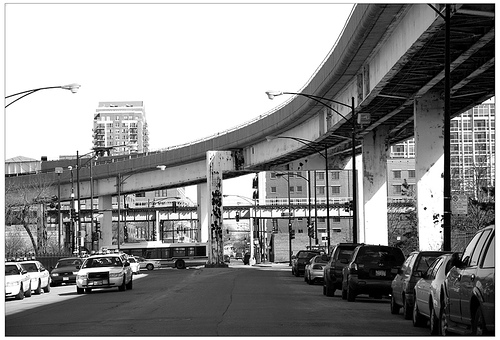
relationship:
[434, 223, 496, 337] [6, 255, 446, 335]
car parked on road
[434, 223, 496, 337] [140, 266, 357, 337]
car on street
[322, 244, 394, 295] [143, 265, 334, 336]
car parked on street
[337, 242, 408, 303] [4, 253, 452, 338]
car parked in street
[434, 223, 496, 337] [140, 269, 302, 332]
car parked in street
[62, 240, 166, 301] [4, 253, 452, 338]
car parked in street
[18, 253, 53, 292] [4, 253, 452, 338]
car parked in street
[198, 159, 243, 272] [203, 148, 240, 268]
graffiti on column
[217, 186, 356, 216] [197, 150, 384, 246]
guard rail on overpass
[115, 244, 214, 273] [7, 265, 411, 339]
bus parked on road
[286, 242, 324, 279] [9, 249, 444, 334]
car is on street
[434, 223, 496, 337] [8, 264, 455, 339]
car is on street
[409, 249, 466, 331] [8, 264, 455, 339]
car is on street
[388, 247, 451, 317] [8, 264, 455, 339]
car is on street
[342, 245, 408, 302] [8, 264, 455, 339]
car is on street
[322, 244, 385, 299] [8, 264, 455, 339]
car is on street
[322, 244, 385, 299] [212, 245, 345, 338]
car is on street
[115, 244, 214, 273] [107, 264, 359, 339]
bus is on street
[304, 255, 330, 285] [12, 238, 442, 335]
car is on road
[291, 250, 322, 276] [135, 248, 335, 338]
car is on road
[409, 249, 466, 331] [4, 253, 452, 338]
car is on street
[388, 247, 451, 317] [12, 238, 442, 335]
car is on road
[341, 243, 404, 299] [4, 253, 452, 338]
vehicle is on street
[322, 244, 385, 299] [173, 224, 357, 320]
car is on street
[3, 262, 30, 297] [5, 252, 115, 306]
vehicle is on side street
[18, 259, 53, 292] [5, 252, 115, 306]
car is on side street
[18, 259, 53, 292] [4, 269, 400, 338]
car is on street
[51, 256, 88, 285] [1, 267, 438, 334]
car is on street